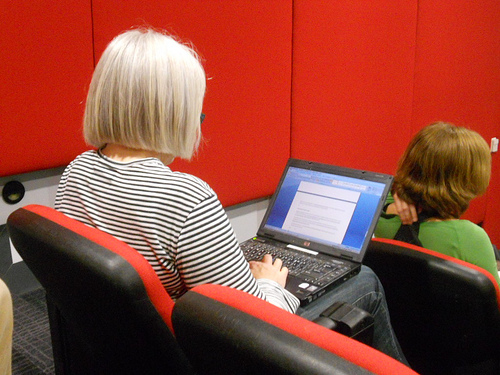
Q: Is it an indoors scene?
A: Yes, it is indoors.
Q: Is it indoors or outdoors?
A: It is indoors.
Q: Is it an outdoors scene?
A: No, it is indoors.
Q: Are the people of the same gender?
A: Yes, all the people are female.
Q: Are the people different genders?
A: No, all the people are female.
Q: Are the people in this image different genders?
A: No, all the people are female.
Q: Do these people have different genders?
A: No, all the people are female.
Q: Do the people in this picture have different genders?
A: No, all the people are female.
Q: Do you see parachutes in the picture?
A: No, there are no parachutes.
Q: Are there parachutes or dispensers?
A: No, there are no parachutes or dispensers.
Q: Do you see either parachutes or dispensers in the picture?
A: No, there are no parachutes or dispensers.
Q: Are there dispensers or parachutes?
A: No, there are no parachutes or dispensers.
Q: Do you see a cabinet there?
A: No, there are no cabinets.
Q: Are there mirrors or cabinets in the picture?
A: No, there are no cabinets or mirrors.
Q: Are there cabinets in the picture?
A: No, there are no cabinets.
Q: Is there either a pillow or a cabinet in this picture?
A: No, there are no cabinets or pillows.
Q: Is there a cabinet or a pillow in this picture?
A: No, there are no cabinets or pillows.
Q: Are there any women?
A: Yes, there is a woman.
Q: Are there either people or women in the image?
A: Yes, there is a woman.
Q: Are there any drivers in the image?
A: No, there are no drivers.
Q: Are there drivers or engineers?
A: No, there are no drivers or engineers.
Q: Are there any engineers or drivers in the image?
A: No, there are no drivers or engineers.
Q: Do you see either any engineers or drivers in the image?
A: No, there are no drivers or engineers.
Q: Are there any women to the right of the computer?
A: Yes, there is a woman to the right of the computer.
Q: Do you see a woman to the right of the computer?
A: Yes, there is a woman to the right of the computer.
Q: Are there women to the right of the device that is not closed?
A: Yes, there is a woman to the right of the computer.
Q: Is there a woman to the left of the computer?
A: No, the woman is to the right of the computer.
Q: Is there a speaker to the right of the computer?
A: No, there is a woman to the right of the computer.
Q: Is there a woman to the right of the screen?
A: Yes, there is a woman to the right of the screen.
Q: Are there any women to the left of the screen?
A: No, the woman is to the right of the screen.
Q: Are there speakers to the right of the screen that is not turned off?
A: No, there is a woman to the right of the screen.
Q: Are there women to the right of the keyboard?
A: Yes, there is a woman to the right of the keyboard.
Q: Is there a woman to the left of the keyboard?
A: No, the woman is to the right of the keyboard.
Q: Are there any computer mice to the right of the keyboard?
A: No, there is a woman to the right of the keyboard.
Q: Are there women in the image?
A: Yes, there is a woman.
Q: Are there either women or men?
A: Yes, there is a woman.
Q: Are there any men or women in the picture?
A: Yes, there is a woman.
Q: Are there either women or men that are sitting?
A: Yes, the woman is sitting.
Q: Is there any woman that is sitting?
A: Yes, there is a woman that is sitting.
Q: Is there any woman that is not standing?
A: Yes, there is a woman that is sitting.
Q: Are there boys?
A: No, there are no boys.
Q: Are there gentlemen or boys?
A: No, there are no boys or gentlemen.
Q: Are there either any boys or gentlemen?
A: No, there are no boys or gentlemen.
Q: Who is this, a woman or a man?
A: This is a woman.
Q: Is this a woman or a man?
A: This is a woman.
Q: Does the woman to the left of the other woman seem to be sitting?
A: Yes, the woman is sitting.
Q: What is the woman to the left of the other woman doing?
A: The woman is sitting.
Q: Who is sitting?
A: The woman is sitting.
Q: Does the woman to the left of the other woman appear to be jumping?
A: No, the woman is sitting.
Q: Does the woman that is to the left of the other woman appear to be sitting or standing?
A: The woman is sitting.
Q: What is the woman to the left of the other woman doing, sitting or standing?
A: The woman is sitting.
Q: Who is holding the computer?
A: The woman is holding the computer.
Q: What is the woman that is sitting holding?
A: The woman is holding the computer.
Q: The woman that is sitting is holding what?
A: The woman is holding the computer.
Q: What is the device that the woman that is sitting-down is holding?
A: The device is a computer.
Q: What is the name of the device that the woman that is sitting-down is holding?
A: The device is a computer.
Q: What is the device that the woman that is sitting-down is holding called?
A: The device is a computer.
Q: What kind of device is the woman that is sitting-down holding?
A: The woman is holding the computer.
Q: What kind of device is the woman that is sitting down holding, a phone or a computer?
A: The woman is holding a computer.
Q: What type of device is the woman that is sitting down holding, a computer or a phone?
A: The woman is holding a computer.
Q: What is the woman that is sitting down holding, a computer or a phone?
A: The woman is holding a computer.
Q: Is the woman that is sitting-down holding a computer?
A: Yes, the woman is holding a computer.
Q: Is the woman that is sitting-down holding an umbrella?
A: No, the woman is holding a computer.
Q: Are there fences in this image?
A: No, there are no fences.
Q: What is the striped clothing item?
A: The clothing item is a shirt.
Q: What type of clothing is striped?
A: The clothing is a shirt.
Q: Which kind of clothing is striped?
A: The clothing is a shirt.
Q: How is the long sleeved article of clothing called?
A: The clothing item is a shirt.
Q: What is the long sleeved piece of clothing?
A: The clothing item is a shirt.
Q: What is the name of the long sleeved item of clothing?
A: The clothing item is a shirt.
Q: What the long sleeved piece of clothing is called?
A: The clothing item is a shirt.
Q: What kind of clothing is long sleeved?
A: The clothing is a shirt.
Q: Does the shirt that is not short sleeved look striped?
A: Yes, the shirt is striped.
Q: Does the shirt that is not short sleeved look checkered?
A: No, the shirt is striped.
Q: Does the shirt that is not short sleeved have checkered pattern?
A: No, the shirt is striped.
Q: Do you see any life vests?
A: No, there are no life vests.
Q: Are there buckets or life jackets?
A: No, there are no life jackets or buckets.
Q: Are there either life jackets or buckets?
A: No, there are no life jackets or buckets.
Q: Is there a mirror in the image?
A: No, there are no mirrors.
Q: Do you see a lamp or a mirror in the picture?
A: No, there are no mirrors or lamps.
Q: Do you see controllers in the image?
A: No, there are no controllers.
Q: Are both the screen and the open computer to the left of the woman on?
A: Yes, both the screen and the computer are on.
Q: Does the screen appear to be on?
A: Yes, the screen is on.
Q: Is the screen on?
A: Yes, the screen is on.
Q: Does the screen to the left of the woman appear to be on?
A: Yes, the screen is on.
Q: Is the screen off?
A: No, the screen is on.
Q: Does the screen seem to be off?
A: No, the screen is on.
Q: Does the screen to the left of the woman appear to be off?
A: No, the screen is on.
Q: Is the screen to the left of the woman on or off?
A: The screen is on.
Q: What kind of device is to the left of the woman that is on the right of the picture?
A: The device is a screen.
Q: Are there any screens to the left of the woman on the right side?
A: Yes, there is a screen to the left of the woman.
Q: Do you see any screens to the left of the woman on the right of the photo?
A: Yes, there is a screen to the left of the woman.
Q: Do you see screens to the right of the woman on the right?
A: No, the screen is to the left of the woman.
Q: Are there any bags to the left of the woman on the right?
A: No, there is a screen to the left of the woman.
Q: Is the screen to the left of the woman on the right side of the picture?
A: Yes, the screen is to the left of the woman.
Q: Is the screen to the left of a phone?
A: No, the screen is to the left of the woman.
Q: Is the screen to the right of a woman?
A: No, the screen is to the left of a woman.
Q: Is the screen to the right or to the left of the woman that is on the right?
A: The screen is to the left of the woman.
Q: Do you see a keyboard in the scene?
A: Yes, there is a keyboard.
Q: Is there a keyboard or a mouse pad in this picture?
A: Yes, there is a keyboard.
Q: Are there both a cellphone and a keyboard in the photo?
A: No, there is a keyboard but no cell phones.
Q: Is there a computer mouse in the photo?
A: No, there are no computer mice.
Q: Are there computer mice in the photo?
A: No, there are no computer mice.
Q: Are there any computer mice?
A: No, there are no computer mice.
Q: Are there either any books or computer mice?
A: No, there are no computer mice or books.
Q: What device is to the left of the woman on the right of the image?
A: The device is a keyboard.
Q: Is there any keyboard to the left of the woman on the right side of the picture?
A: Yes, there is a keyboard to the left of the woman.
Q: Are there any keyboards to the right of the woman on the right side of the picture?
A: No, the keyboard is to the left of the woman.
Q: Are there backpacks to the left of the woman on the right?
A: No, there is a keyboard to the left of the woman.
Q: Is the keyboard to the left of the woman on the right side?
A: Yes, the keyboard is to the left of the woman.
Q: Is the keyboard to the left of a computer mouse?
A: No, the keyboard is to the left of the woman.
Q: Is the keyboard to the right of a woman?
A: No, the keyboard is to the left of a woman.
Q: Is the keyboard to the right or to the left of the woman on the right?
A: The keyboard is to the left of the woman.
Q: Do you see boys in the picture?
A: No, there are no boys.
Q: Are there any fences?
A: No, there are no fences.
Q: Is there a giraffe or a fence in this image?
A: No, there are no fences or giraffes.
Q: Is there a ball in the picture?
A: No, there are no balls.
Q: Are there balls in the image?
A: No, there are no balls.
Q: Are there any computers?
A: Yes, there is a computer.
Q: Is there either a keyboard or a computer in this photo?
A: Yes, there is a computer.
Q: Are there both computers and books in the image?
A: No, there is a computer but no books.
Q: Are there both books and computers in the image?
A: No, there is a computer but no books.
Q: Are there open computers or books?
A: Yes, there is an open computer.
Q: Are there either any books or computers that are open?
A: Yes, the computer is open.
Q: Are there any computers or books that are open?
A: Yes, the computer is open.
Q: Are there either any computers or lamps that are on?
A: Yes, the computer is on.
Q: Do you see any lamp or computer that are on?
A: Yes, the computer is on.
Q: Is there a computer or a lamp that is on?
A: Yes, the computer is on.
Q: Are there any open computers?
A: Yes, there is an open computer.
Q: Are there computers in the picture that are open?
A: Yes, there is a computer that is open.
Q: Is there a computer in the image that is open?
A: Yes, there is a computer that is open.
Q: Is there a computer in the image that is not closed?
A: Yes, there is a open computer.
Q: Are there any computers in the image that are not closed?
A: Yes, there is a open computer.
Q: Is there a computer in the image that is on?
A: Yes, there is a computer that is on.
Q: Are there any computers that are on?
A: Yes, there is a computer that is on.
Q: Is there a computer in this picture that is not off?
A: Yes, there is a computer that is on.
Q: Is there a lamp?
A: No, there are no lamps.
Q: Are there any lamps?
A: No, there are no lamps.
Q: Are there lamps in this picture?
A: No, there are no lamps.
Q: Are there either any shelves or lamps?
A: No, there are no lamps or shelves.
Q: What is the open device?
A: The device is a computer.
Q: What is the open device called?
A: The device is a computer.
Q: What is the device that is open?
A: The device is a computer.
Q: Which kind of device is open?
A: The device is a computer.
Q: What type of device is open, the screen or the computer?
A: The computer is open.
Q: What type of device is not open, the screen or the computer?
A: The screen is not open.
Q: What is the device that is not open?
A: The device is a screen.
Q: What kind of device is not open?
A: The device is a screen.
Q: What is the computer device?
A: The device is a computer.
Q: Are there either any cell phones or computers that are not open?
A: No, there is a computer but it is open.